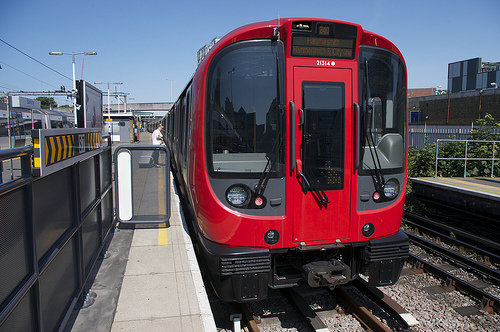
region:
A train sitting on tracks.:
[18, 4, 490, 330]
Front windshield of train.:
[196, 17, 296, 220]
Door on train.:
[286, 12, 359, 257]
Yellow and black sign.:
[34, 130, 111, 170]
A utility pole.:
[44, 40, 99, 125]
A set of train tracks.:
[412, 220, 496, 305]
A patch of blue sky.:
[101, 7, 180, 72]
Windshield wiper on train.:
[241, 120, 294, 207]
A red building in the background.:
[408, 40, 498, 127]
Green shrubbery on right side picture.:
[411, 117, 499, 179]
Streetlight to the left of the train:
[47, 48, 104, 128]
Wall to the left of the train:
[2, 181, 119, 327]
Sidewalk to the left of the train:
[133, 246, 195, 329]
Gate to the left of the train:
[110, 141, 173, 236]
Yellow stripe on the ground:
[153, 167, 170, 252]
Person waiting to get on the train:
[146, 118, 169, 169]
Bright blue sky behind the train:
[11, 7, 195, 44]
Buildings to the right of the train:
[408, 56, 498, 119]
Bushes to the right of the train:
[411, 113, 497, 179]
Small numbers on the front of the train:
[311, 58, 342, 69]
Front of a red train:
[201, 18, 407, 303]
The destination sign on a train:
[283, 17, 359, 64]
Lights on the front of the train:
[218, 178, 407, 208]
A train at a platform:
[170, 16, 422, 329]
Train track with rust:
[428, 238, 490, 314]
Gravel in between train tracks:
[397, 290, 481, 317]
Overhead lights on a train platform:
[31, 43, 152, 110]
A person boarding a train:
[132, 119, 182, 176]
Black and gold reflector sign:
[35, 128, 112, 178]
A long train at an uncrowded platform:
[112, 18, 409, 315]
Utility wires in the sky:
[2, 36, 79, 98]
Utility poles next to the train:
[41, 47, 133, 114]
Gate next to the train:
[103, 138, 183, 238]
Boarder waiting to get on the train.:
[139, 113, 176, 172]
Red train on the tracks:
[173, 12, 448, 310]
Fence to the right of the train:
[431, 136, 498, 179]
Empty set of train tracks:
[407, 209, 499, 302]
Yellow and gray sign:
[23, 123, 113, 172]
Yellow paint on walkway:
[153, 164, 170, 249]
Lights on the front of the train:
[216, 178, 411, 253]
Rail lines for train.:
[421, 223, 492, 298]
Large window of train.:
[205, 31, 298, 183]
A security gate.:
[18, 105, 168, 316]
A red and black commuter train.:
[178, 12, 410, 291]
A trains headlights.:
[212, 165, 417, 221]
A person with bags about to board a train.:
[131, 116, 166, 169]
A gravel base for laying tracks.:
[404, 282, 446, 319]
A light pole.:
[49, 39, 106, 88]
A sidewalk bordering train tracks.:
[116, 230, 199, 323]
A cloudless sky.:
[17, 3, 195, 108]